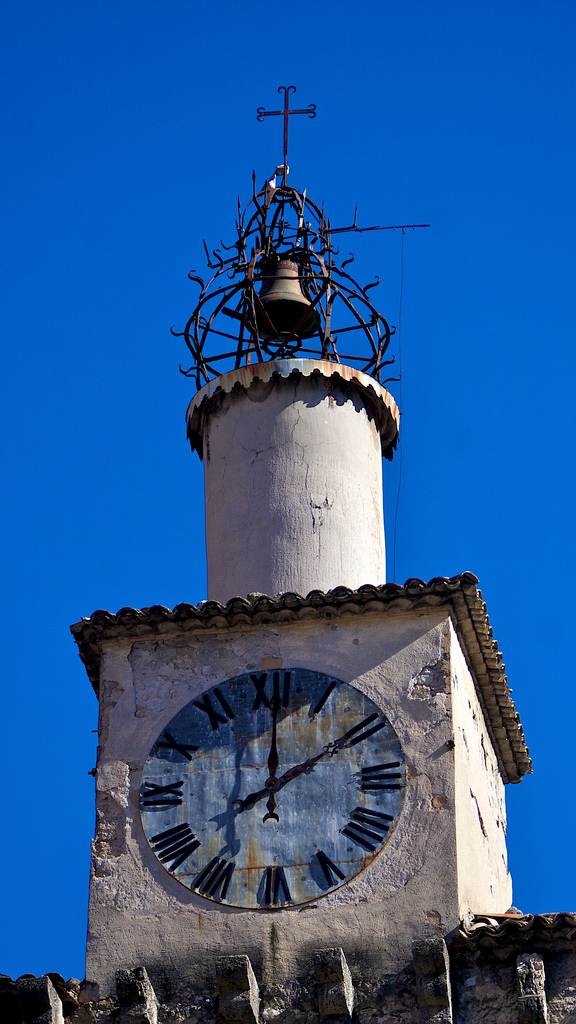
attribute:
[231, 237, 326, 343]
bell — rusty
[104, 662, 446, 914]
clock — white, black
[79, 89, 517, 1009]
building — white, tall, rusty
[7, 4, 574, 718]
sky — blue